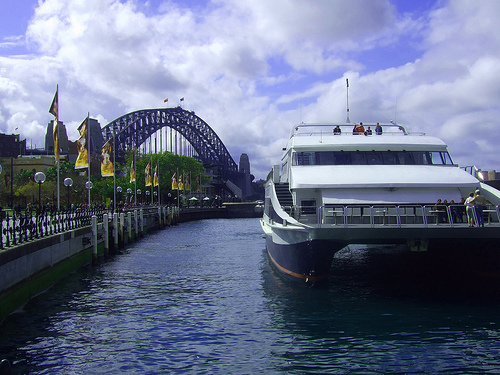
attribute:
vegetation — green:
[2, 155, 211, 205]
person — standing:
[475, 186, 484, 229]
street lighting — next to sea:
[31, 167, 168, 199]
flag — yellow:
[74, 115, 89, 168]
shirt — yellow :
[467, 192, 489, 207]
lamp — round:
[33, 167, 48, 227]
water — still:
[66, 280, 498, 373]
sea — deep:
[16, 266, 497, 374]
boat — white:
[263, 107, 498, 326]